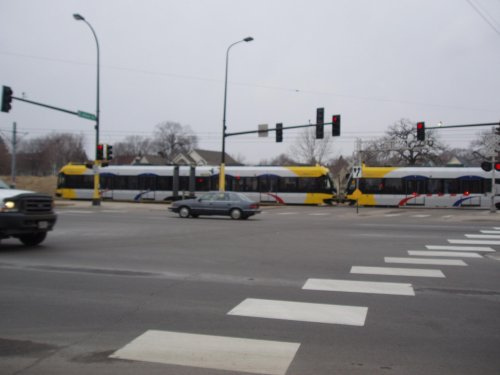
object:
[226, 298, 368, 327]
box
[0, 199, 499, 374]
road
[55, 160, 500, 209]
train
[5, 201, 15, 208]
headlight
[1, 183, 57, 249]
truck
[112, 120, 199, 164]
trees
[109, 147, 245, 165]
house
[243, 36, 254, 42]
street light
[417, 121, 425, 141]
traffic light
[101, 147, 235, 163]
roofs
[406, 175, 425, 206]
door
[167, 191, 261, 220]
car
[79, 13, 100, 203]
post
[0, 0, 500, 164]
sky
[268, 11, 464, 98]
clouds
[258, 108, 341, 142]
signals